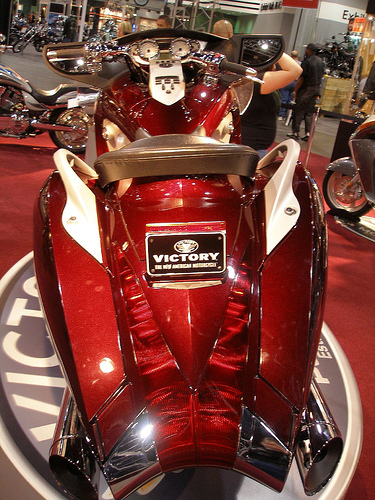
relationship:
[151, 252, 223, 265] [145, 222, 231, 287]
name on plate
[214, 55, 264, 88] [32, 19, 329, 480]
handle on motorcycle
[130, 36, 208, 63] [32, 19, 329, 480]
panel on motorcycle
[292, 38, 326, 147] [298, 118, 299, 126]
man in black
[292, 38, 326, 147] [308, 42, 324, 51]
man has hat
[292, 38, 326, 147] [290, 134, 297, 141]
man wearing sneaker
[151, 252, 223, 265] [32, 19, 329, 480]
name on motorcycle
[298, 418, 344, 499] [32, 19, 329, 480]
exhaust pipe on motorcycle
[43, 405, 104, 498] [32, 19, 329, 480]
exhaust pipe on motorcycle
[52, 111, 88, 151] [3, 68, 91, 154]
tire on motorcycle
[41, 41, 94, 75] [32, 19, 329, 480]
mirror on motorcycle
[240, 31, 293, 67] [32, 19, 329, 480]
mirror on motorcycle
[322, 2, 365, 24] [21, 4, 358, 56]
sign in hall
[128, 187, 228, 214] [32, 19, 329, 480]
reflection on motorcycle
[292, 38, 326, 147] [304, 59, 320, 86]
man has shirt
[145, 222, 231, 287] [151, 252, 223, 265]
plate has name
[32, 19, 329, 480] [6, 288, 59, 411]
motorcycle on exhibit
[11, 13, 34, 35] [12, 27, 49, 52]
group of motorcycle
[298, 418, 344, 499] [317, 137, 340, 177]
exhaust pipe on right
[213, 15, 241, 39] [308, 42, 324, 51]
man wearing hat